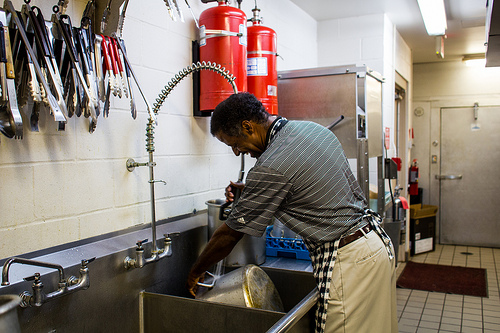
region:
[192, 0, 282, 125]
Two large fire extinguishers are hanging on the wall above the sink.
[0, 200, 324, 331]
The sink is stainless steel.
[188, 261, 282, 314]
The man is washing a large pot.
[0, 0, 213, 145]
the rack above the sink has many sets of tongs hanging on it.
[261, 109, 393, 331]
The man is wearing a checkered apron.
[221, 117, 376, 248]
The man is wearing a grey striped shirt.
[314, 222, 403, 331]
The man is wearing khaki pants.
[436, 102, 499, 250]
The freezer door in the background is closed.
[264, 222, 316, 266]
The rack on the sink holding dishes is blue.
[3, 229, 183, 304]
The sink has two faucets.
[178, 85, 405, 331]
person standing next to a sink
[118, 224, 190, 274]
faucets on a sink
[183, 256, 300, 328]
a pot in a sink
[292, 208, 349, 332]
white and black apron around a persons waist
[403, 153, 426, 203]
fire extinguisher on a wall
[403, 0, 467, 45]
a light on a ceiling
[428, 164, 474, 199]
a handle on a door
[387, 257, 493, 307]
a carpet on a floor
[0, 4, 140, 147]
kitchen utensils hanging on a wall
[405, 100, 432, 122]
a clock on a wall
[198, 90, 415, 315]
a man washing a pot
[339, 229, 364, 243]
a brown leather belt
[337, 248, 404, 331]
a person in tan pants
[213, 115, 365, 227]
a man wearing a short sleeved shirt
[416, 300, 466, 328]
tiles on the floor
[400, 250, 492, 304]
a carpet on a tiled floor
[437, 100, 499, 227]
the door to a walk in cooler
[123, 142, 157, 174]
a faucet fastened to a wall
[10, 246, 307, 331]
dual basin sink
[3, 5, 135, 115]
cooking utensils hanging on a wall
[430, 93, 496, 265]
Gray door is in the background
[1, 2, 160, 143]
Cooking tools are on the wall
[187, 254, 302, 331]
Large gray pot is in the big sink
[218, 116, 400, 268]
Man is wearing a gray striped shirt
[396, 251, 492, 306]
Dark brown rug is on the tile floor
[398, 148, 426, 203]
Red fire extinguisher is in the background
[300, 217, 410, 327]
Man is wearing khaki pants with brown belt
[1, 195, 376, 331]
Large gray metal sink for cooking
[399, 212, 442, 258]
Black box object in background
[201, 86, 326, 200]
Man has black hair with gray on the side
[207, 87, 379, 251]
man is wearing a striped shirt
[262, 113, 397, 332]
man is wearing a checkered apron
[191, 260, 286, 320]
huge cooking pot in the sink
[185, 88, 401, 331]
man is washing a pot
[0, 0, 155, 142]
many utensils hang above the sink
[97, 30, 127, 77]
red handles of kitchen utensils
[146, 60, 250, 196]
tap has a coil around it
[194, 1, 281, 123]
two red tanks on the kitchen wall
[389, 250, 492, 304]
a brown mat on the floor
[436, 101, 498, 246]
a large heavy door at the end of a a kitchen